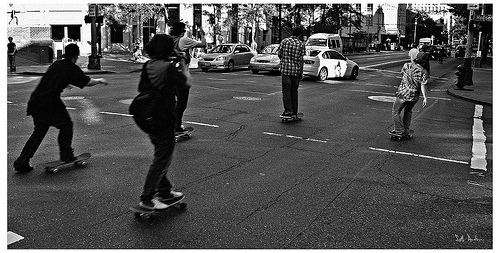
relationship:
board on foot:
[126, 191, 184, 230] [147, 191, 174, 211]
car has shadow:
[305, 46, 366, 82] [308, 52, 329, 76]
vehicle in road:
[252, 34, 280, 84] [0, 70, 500, 249]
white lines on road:
[472, 104, 485, 174] [0, 70, 500, 249]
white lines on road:
[368, 147, 470, 171] [0, 70, 500, 249]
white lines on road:
[259, 129, 329, 146] [0, 70, 500, 249]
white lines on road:
[178, 123, 220, 127] [0, 70, 500, 249]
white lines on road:
[96, 113, 134, 115] [0, 70, 500, 249]